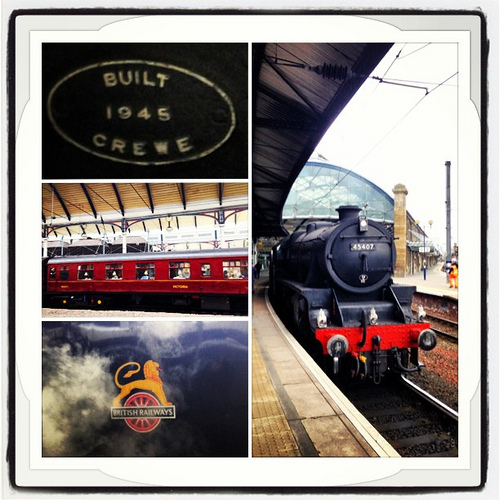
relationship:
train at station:
[262, 213, 444, 384] [267, 152, 462, 469]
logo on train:
[354, 271, 372, 289] [262, 213, 444, 384]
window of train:
[130, 264, 161, 285] [43, 247, 257, 309]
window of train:
[167, 263, 194, 282] [262, 213, 444, 384]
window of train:
[106, 263, 125, 281] [43, 247, 257, 309]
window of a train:
[130, 264, 161, 285] [43, 247, 257, 309]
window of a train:
[167, 263, 194, 282] [43, 247, 257, 309]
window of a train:
[106, 263, 125, 281] [43, 247, 257, 309]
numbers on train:
[349, 242, 377, 250] [262, 213, 444, 384]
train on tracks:
[262, 213, 444, 384] [340, 356, 469, 460]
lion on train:
[99, 353, 183, 433] [45, 325, 249, 463]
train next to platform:
[262, 213, 444, 384] [254, 266, 395, 458]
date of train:
[107, 107, 170, 121] [262, 213, 444, 384]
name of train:
[111, 408, 175, 421] [45, 325, 249, 463]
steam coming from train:
[340, 160, 369, 203] [262, 213, 444, 384]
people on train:
[141, 269, 191, 280] [262, 213, 444, 384]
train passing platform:
[262, 213, 444, 384] [254, 266, 395, 458]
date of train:
[106, 103, 183, 122] [262, 213, 444, 384]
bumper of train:
[313, 324, 437, 359] [262, 213, 444, 384]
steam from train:
[340, 160, 369, 203] [262, 213, 444, 384]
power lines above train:
[302, 62, 436, 215] [262, 213, 444, 384]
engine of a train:
[267, 232, 394, 307] [262, 213, 444, 384]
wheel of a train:
[54, 297, 93, 307] [43, 247, 257, 309]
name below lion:
[111, 408, 175, 421] [99, 353, 183, 433]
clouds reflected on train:
[49, 343, 111, 418] [45, 325, 249, 463]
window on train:
[130, 264, 161, 285] [43, 247, 257, 309]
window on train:
[167, 263, 194, 282] [43, 247, 257, 309]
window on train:
[106, 263, 125, 281] [43, 247, 257, 309]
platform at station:
[254, 266, 395, 458] [267, 152, 462, 469]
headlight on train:
[359, 219, 379, 231] [262, 213, 444, 384]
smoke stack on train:
[336, 203, 366, 219] [262, 213, 444, 384]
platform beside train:
[254, 266, 395, 458] [262, 213, 444, 384]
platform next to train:
[254, 266, 395, 458] [262, 213, 444, 384]